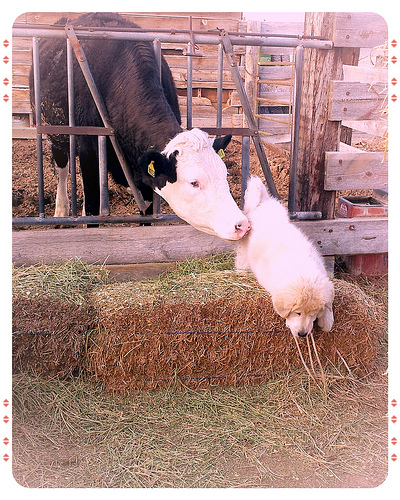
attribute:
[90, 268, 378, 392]
hay — bale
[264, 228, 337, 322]
dog — white 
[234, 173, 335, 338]
puppy — keeping company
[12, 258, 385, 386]
grain — hay stick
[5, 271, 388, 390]
hay — bale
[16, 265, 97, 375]
hay — bale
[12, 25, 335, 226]
fence — METAL, wooden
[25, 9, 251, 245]
cow — keeping company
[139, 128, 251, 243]
head — white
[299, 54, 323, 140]
wooden — fence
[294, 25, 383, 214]
fence — wooden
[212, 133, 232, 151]
ear — black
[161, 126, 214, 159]
hair — white, tuft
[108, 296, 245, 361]
grain — hay stick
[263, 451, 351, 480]
dirt — ground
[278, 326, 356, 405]
hay stick — of hay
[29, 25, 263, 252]
bull — black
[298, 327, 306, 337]
nose — black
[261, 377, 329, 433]
grain — hay stick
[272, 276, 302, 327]
ears — floppy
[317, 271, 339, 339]
ears — floppy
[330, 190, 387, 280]
container — red, metal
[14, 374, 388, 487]
straw — green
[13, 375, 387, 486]
grass — green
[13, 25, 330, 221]
gate — metal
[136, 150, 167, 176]
ear — black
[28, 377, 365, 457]
grain — hay stick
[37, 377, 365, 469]
grain — hay stick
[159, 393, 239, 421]
grain — hay stick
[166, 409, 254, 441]
grain — hay stick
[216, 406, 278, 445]
grain — hay stick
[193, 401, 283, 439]
grain — hay stick